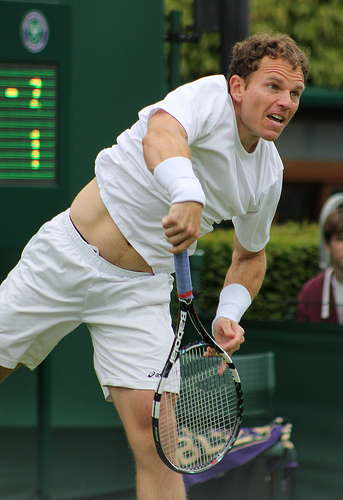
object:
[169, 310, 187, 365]
name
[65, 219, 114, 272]
band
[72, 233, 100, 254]
string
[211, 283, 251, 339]
band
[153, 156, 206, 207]
band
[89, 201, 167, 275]
belly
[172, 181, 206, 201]
wrist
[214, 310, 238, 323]
wrist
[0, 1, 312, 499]
game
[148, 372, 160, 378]
logo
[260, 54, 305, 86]
forhead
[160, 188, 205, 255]
hand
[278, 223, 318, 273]
hedges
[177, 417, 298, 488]
banner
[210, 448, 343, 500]
ground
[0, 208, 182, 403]
shorts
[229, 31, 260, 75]
hair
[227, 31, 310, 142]
head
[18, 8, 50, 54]
logo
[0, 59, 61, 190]
scoreboard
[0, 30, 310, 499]
man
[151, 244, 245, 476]
racket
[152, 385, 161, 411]
strings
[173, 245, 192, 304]
handle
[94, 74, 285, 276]
shirt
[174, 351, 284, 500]
chair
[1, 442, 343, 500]
court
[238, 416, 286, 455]
towel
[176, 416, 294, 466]
lettering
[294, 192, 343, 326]
man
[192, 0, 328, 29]
hedges